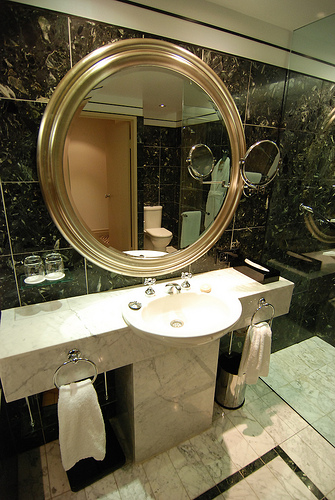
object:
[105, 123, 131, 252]
bathroom door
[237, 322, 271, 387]
towel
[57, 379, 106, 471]
towel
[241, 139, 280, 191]
mirror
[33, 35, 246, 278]
mirror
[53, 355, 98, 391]
ring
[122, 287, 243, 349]
basin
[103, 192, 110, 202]
doorknob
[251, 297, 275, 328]
hanger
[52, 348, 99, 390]
hanger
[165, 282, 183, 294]
faucet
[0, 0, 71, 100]
marble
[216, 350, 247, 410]
trash bin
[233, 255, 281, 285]
box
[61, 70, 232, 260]
reflection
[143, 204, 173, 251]
toilet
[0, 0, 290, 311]
wall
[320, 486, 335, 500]
tile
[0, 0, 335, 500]
bathroom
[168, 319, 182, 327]
drain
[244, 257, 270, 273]
tissues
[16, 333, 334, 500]
floor